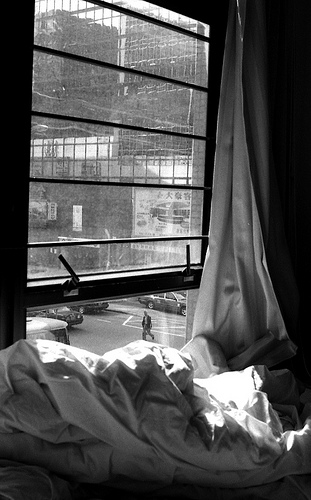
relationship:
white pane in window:
[35, 41, 207, 158] [32, 3, 206, 336]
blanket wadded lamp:
[1, 335, 310, 483] [91, 346, 230, 446]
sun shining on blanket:
[156, 296, 182, 348] [1, 335, 310, 483]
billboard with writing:
[132, 191, 190, 242] [155, 192, 164, 199]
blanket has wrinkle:
[1, 335, 310, 483] [99, 353, 141, 400]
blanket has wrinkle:
[1, 335, 310, 483] [38, 354, 93, 393]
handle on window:
[54, 247, 81, 292] [23, 0, 203, 309]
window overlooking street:
[19, 0, 222, 382] [22, 258, 189, 367]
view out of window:
[24, 227, 195, 331] [26, 0, 210, 278]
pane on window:
[29, 10, 206, 287] [19, 0, 222, 382]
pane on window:
[29, 10, 206, 287] [26, 0, 210, 278]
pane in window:
[174, 153, 188, 179] [171, 101, 218, 176]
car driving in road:
[26, 303, 82, 330] [26, 287, 189, 356]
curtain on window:
[190, 0, 302, 368] [19, 0, 222, 382]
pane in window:
[28, 38, 60, 59] [19, 0, 222, 382]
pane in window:
[29, 179, 205, 238] [31, 3, 226, 343]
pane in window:
[29, 10, 206, 287] [31, 3, 226, 343]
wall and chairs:
[34, 0, 211, 267] [139, 252, 156, 264]